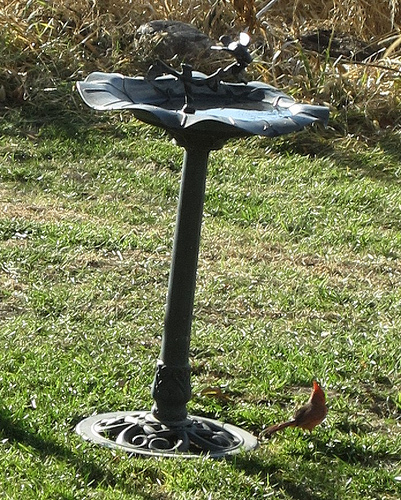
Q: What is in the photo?
A: A fountain.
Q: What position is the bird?
A: On the ground.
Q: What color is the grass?
A: Green.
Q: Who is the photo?
A: Noone.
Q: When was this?
A: Daytime.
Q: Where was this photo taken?
A: In the backyard.